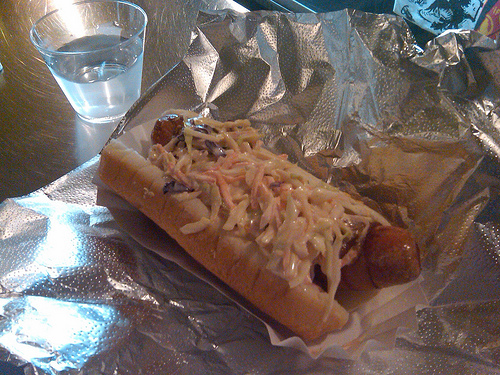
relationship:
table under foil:
[1, 1, 241, 203] [1, 8, 498, 374]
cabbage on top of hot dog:
[150, 106, 371, 305] [152, 114, 420, 289]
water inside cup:
[49, 35, 146, 123] [30, 1, 153, 122]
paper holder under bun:
[92, 107, 430, 359] [92, 107, 391, 340]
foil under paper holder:
[1, 8, 498, 374] [92, 107, 430, 359]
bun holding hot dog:
[92, 107, 391, 340] [152, 114, 420, 289]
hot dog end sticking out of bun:
[339, 225, 424, 288] [92, 107, 391, 340]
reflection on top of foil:
[1, 192, 119, 373] [1, 8, 498, 374]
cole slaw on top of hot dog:
[151, 115, 372, 323] [152, 114, 420, 289]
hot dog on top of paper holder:
[152, 114, 420, 289] [92, 107, 430, 359]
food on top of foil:
[95, 108, 423, 341] [1, 8, 498, 374]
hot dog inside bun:
[152, 114, 420, 289] [92, 107, 391, 340]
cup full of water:
[30, 1, 153, 122] [49, 35, 146, 123]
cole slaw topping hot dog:
[151, 115, 372, 323] [152, 114, 420, 289]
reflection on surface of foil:
[1, 192, 119, 373] [1, 8, 498, 374]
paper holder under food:
[92, 107, 430, 359] [95, 108, 423, 341]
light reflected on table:
[49, 1, 85, 38] [1, 1, 241, 203]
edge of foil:
[197, 9, 498, 96] [1, 8, 498, 374]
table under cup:
[1, 1, 241, 203] [30, 1, 153, 122]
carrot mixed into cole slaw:
[202, 169, 234, 208] [151, 115, 372, 323]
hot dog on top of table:
[152, 114, 420, 289] [1, 1, 241, 203]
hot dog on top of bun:
[152, 114, 420, 289] [92, 107, 391, 340]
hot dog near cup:
[152, 114, 420, 289] [30, 1, 153, 122]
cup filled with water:
[30, 1, 153, 122] [49, 35, 146, 123]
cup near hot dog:
[30, 1, 153, 122] [152, 114, 420, 289]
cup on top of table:
[30, 1, 153, 122] [1, 1, 241, 203]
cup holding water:
[30, 1, 153, 122] [49, 35, 146, 123]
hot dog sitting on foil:
[152, 114, 420, 289] [1, 8, 498, 374]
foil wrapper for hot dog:
[1, 8, 498, 374] [152, 114, 420, 289]